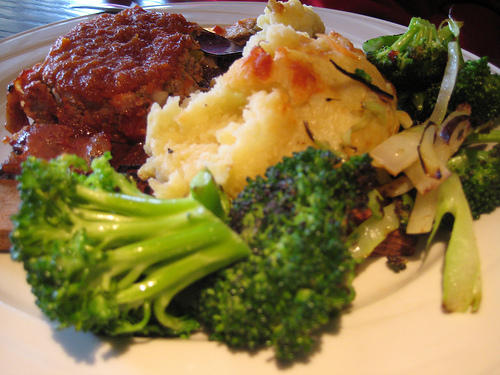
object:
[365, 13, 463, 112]
broccoli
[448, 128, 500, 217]
broccoli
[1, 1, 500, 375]
dish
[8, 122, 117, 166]
stew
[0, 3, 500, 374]
meal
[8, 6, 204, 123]
meat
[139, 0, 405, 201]
mash potatoes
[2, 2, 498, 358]
food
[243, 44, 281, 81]
spots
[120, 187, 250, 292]
stem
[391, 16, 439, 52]
stem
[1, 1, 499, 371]
plate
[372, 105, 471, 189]
onions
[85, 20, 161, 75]
tomato sauce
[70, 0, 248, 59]
fork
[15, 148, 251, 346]
broccoli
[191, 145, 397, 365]
broccoli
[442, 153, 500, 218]
broccoli crown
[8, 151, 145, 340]
broccoli crown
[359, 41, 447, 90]
broccoli crown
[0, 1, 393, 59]
table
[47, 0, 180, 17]
light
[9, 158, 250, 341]
plants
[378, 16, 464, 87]
plants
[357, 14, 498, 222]
vegetables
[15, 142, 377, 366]
vegetables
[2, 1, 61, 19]
wood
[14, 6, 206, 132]
meatloaf